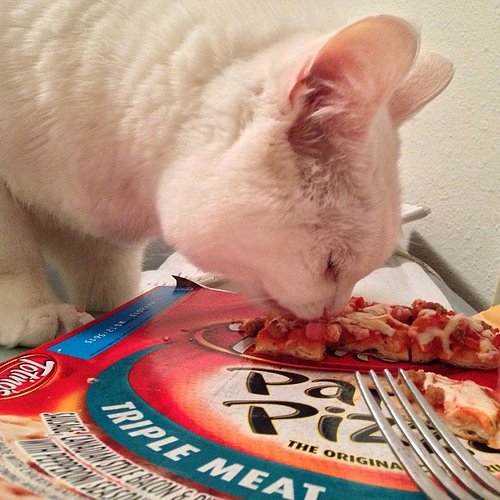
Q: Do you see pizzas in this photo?
A: Yes, there is a pizza.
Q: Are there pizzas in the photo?
A: Yes, there is a pizza.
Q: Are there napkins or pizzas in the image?
A: Yes, there is a pizza.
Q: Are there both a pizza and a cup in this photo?
A: No, there is a pizza but no cups.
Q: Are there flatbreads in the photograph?
A: No, there are no flatbreads.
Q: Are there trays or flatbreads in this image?
A: No, there are no flatbreads or trays.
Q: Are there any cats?
A: Yes, there is a cat.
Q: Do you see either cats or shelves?
A: Yes, there is a cat.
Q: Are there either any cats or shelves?
A: Yes, there is a cat.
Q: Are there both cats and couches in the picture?
A: No, there is a cat but no couches.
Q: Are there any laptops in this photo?
A: No, there are no laptops.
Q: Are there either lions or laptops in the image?
A: No, there are no laptops or lions.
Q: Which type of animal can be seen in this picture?
A: The animal is a cat.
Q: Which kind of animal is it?
A: The animal is a cat.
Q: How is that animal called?
A: That is a cat.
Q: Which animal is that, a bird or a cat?
A: That is a cat.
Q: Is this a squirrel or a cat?
A: This is a cat.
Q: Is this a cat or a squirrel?
A: This is a cat.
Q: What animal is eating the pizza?
A: The cat is eating the pizza.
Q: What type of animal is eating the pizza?
A: The animal is a cat.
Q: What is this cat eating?
A: The cat is eating a pizza.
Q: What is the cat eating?
A: The cat is eating a pizza.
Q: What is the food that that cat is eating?
A: The food is a pizza.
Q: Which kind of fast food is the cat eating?
A: The cat is eating a pizza.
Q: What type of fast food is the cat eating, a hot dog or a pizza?
A: The cat is eating a pizza.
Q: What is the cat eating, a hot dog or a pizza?
A: The cat is eating a pizza.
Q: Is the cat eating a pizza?
A: Yes, the cat is eating a pizza.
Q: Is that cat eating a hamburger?
A: No, the cat is eating a pizza.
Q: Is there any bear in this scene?
A: No, there are no bears.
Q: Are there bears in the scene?
A: No, there are no bears.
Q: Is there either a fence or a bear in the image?
A: No, there are no bears or fences.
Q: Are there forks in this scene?
A: Yes, there is a fork.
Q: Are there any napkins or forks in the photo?
A: Yes, there is a fork.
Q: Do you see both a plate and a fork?
A: No, there is a fork but no plates.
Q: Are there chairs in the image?
A: No, there are no chairs.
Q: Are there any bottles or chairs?
A: No, there are no chairs or bottles.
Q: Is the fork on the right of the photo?
A: Yes, the fork is on the right of the image.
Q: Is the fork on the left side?
A: No, the fork is on the right of the image.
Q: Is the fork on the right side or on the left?
A: The fork is on the right of the image.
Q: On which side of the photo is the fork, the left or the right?
A: The fork is on the right of the image.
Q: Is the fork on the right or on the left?
A: The fork is on the right of the image.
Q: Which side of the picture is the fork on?
A: The fork is on the right of the image.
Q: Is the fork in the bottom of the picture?
A: Yes, the fork is in the bottom of the image.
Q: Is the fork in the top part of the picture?
A: No, the fork is in the bottom of the image.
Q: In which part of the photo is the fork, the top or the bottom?
A: The fork is in the bottom of the image.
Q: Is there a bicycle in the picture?
A: No, there are no bicycles.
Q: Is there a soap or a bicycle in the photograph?
A: No, there are no bicycles or soaps.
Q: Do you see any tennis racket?
A: No, there are no rackets.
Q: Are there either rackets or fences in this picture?
A: No, there are no rackets or fences.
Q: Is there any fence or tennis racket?
A: No, there are no rackets or fences.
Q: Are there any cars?
A: No, there are no cars.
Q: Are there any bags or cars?
A: No, there are no cars or bags.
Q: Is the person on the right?
A: Yes, the person is on the right of the image.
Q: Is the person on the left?
A: No, the person is on the right of the image.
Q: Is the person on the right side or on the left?
A: The person is on the right of the image.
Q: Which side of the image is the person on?
A: The person is on the right of the image.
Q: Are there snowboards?
A: No, there are no snowboards.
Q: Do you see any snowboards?
A: No, there are no snowboards.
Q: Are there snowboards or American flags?
A: No, there are no snowboards or American flags.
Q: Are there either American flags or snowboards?
A: No, there are no snowboards or American flags.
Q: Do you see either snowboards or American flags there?
A: No, there are no snowboards or American flags.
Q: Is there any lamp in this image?
A: No, there are no lamps.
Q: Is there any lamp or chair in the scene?
A: No, there are no lamps or chairs.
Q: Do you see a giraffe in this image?
A: No, there are no giraffes.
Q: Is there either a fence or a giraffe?
A: No, there are no giraffes or fences.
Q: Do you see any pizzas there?
A: Yes, there is a pizza.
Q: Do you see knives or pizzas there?
A: Yes, there is a pizza.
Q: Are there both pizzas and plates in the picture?
A: No, there is a pizza but no plates.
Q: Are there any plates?
A: No, there are no plates.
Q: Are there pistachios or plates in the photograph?
A: No, there are no plates or pistachios.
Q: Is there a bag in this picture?
A: No, there are no bags.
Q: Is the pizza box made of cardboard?
A: Yes, the pizza box is made of cardboard.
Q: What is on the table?
A: The pizza box is on the table.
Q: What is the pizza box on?
A: The pizza box is on the table.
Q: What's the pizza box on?
A: The pizza box is on the table.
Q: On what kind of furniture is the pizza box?
A: The pizza box is on the table.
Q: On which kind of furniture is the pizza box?
A: The pizza box is on the table.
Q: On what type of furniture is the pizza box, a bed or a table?
A: The pizza box is on a table.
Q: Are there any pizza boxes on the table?
A: Yes, there is a pizza box on the table.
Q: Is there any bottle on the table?
A: No, there is a pizza box on the table.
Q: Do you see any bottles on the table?
A: No, there is a pizza box on the table.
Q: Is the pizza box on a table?
A: Yes, the pizza box is on a table.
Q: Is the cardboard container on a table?
A: Yes, the pizza box is on a table.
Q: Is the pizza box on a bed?
A: No, the pizza box is on a table.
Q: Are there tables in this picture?
A: Yes, there is a table.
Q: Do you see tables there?
A: Yes, there is a table.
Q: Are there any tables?
A: Yes, there is a table.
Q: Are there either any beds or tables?
A: Yes, there is a table.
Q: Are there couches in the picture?
A: No, there are no couches.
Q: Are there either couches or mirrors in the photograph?
A: No, there are no couches or mirrors.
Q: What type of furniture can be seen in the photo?
A: The furniture is a table.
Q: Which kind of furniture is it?
A: The piece of furniture is a table.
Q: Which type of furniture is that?
A: This is a table.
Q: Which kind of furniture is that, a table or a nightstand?
A: This is a table.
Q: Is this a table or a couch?
A: This is a table.